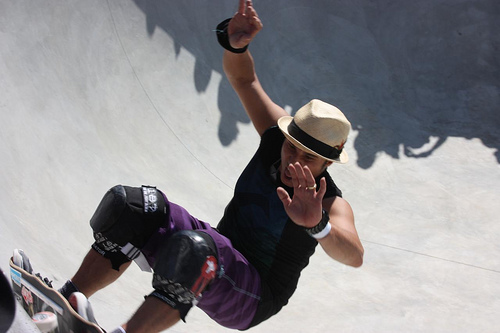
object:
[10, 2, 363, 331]
man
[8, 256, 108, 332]
skateboard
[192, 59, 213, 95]
shadow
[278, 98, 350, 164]
hat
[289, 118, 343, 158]
stripe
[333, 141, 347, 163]
feather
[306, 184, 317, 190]
ring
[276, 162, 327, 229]
hand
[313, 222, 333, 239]
bracelet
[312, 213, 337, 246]
wrist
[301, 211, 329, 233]
bracelet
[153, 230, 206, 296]
pad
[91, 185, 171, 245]
pad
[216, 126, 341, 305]
top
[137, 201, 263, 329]
shorts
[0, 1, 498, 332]
wall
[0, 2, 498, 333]
park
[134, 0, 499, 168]
shadow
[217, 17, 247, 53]
watch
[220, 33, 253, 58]
wrist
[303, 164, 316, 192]
finger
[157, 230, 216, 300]
knee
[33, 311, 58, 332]
wheel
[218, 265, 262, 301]
stripe